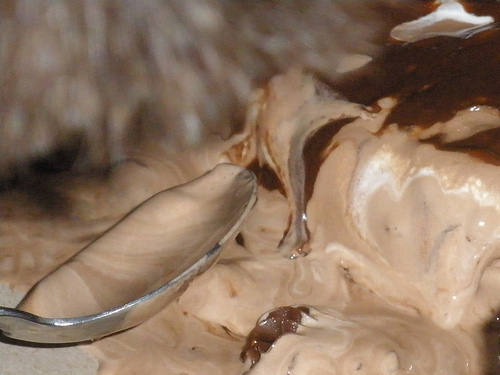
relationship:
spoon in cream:
[0, 162, 268, 346] [90, 14, 500, 374]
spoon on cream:
[0, 162, 268, 346] [90, 14, 500, 374]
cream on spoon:
[90, 14, 500, 374] [0, 162, 268, 346]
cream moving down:
[90, 14, 500, 374] [259, 81, 388, 290]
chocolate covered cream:
[332, 35, 496, 142] [90, 14, 500, 374]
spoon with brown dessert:
[0, 162, 268, 346] [128, 119, 339, 374]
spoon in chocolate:
[0, 162, 268, 346] [332, 35, 496, 142]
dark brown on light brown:
[277, 37, 499, 372] [378, 178, 499, 300]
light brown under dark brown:
[378, 178, 499, 300] [332, 35, 496, 142]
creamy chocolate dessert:
[260, 163, 434, 331] [90, 14, 500, 374]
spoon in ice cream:
[0, 162, 268, 346] [277, 37, 499, 372]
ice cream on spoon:
[277, 37, 499, 372] [0, 162, 268, 346]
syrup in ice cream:
[289, 21, 499, 251] [277, 37, 499, 372]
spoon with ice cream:
[0, 162, 268, 346] [277, 37, 499, 372]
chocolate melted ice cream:
[332, 35, 496, 142] [277, 37, 499, 372]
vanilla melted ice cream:
[54, 237, 484, 371] [277, 37, 499, 372]